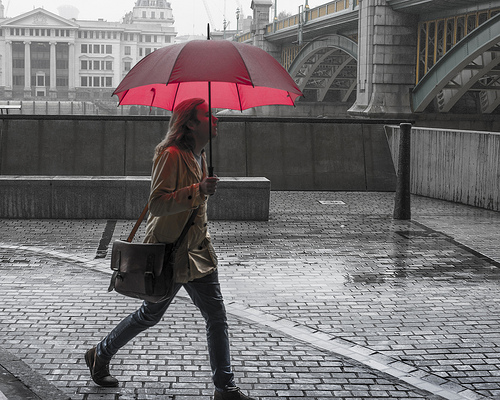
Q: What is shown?
A: A person walking.